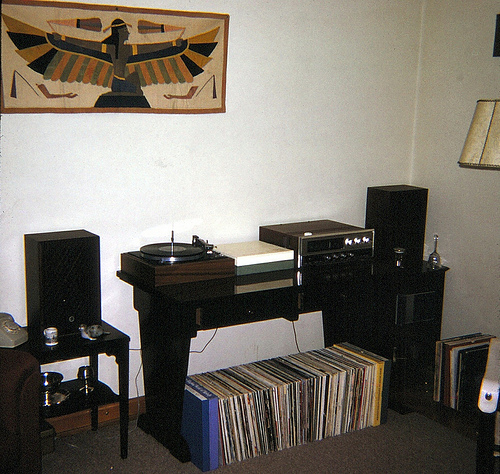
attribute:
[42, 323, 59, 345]
white cup — little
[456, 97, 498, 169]
lampshade — beige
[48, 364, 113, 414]
items — silver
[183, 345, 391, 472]
records — old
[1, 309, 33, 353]
telephone — beige, rotary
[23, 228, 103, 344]
speaker — jet black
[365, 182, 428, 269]
speaker — jet black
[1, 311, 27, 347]
phone — grey, rotary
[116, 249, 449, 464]
desk — black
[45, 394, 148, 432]
baseboard — brown, wooden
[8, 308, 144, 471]
table — small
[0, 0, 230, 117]
frame — wooden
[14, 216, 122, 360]
speaker — black, stereo